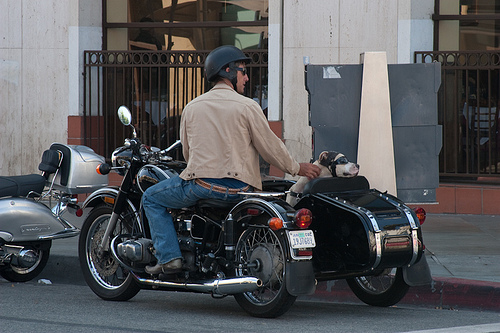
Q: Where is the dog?
A: In the motorcycle side car.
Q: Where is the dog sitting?
A: A sidecar.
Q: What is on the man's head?
A: A helmet.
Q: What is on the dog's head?
A: A helmet.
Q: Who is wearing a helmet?
A: The man and the dog.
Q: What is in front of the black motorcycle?
A: A silver motorcycle.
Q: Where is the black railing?
A: Between the stone pillars.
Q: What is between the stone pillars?
A: A black railing.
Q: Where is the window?
A: Behind the railing.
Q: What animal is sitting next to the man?
A: A dog.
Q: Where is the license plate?
A: Back of the motorcycle.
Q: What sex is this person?
A: Male.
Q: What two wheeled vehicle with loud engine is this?
A: Motorcycle.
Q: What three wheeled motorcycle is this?
A: Trike.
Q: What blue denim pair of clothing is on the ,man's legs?
A: Jeans.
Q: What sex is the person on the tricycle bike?
A: Male.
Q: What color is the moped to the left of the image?
A: Silver.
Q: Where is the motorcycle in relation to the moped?
A: Behind it.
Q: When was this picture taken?
A: Day time.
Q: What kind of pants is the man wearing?
A: Jeans.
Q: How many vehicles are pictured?
A: Two.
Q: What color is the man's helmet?
A: Black.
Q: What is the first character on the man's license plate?
A: Z.